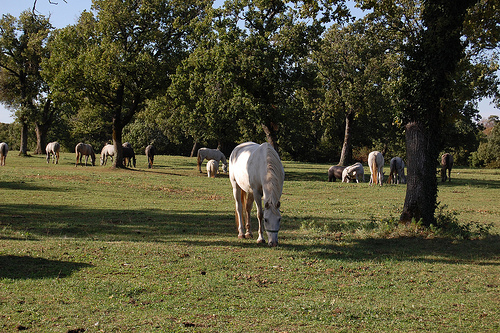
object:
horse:
[44, 141, 61, 165]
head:
[260, 201, 283, 247]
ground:
[417, 117, 433, 137]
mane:
[264, 148, 284, 216]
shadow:
[280, 211, 497, 272]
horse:
[121, 141, 137, 167]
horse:
[98, 142, 114, 166]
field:
[1, 144, 495, 330]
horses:
[386, 156, 407, 184]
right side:
[395, 119, 407, 222]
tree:
[307, 0, 500, 220]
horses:
[228, 140, 286, 247]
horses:
[367, 150, 385, 187]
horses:
[341, 162, 365, 183]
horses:
[197, 146, 229, 173]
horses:
[74, 142, 96, 168]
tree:
[0, 9, 57, 157]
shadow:
[0, 201, 235, 243]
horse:
[144, 137, 162, 168]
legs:
[231, 183, 245, 234]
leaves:
[68, 41, 124, 87]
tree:
[41, 35, 169, 164]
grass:
[0, 144, 498, 329]